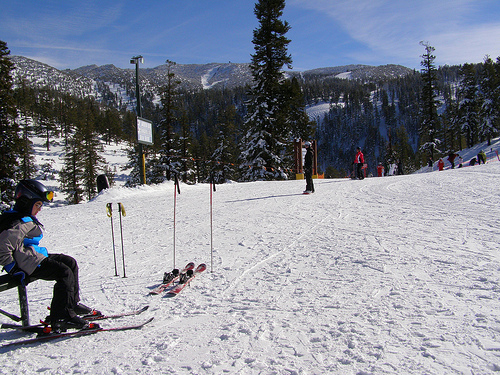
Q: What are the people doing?
A: Skiing.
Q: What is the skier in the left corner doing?
A: Sitting.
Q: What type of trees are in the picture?
A: Pine.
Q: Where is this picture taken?
A: A ski slope.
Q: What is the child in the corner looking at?
A: The ground.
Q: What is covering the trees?
A: Snow.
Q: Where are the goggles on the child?
A: On the forehead.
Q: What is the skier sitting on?
A: Bench.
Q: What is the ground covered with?
A: Snow.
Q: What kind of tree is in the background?
A: Evergreen.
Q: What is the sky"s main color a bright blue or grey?
A: Bright blue.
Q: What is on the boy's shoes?
A: Skis.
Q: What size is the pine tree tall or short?
A: Tall.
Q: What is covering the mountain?
A: Snow.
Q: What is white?
A: Snow.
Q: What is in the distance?
A: Mountains.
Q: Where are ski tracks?
A: On the snow.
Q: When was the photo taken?
A: Daytime.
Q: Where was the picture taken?
A: At a ski slope.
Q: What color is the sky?
A: Blue.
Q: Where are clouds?
A: In the sky.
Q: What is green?
A: Trees.